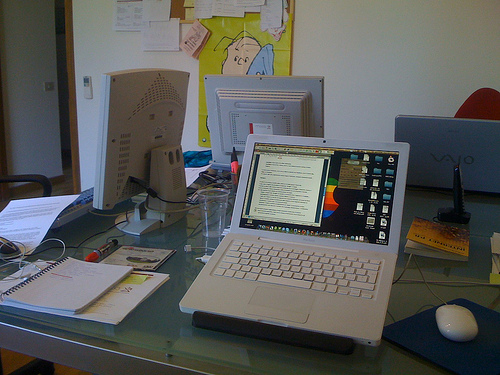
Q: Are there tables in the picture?
A: Yes, there is a table.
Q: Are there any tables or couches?
A: Yes, there is a table.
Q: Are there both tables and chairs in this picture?
A: Yes, there are both a table and a chair.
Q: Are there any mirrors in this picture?
A: No, there are no mirrors.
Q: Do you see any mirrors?
A: No, there are no mirrors.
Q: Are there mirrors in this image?
A: No, there are no mirrors.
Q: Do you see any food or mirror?
A: No, there are no mirrors or food.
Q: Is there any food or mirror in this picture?
A: No, there are no mirrors or food.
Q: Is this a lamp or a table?
A: This is a table.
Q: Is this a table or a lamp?
A: This is a table.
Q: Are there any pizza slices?
A: No, there are no pizza slices.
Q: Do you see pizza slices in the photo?
A: No, there are no pizza slices.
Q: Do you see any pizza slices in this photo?
A: No, there are no pizza slices.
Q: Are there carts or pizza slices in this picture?
A: No, there are no pizza slices or carts.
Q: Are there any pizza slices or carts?
A: No, there are no pizza slices or carts.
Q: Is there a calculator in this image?
A: No, there are no calculators.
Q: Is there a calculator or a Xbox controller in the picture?
A: No, there are no calculators or Xbox controllers.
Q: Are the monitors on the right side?
A: No, the monitors are on the left of the image.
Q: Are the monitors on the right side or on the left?
A: The monitors are on the left of the image.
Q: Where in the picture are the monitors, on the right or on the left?
A: The monitors are on the left of the image.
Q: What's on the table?
A: The monitors are on the table.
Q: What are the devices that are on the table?
A: The devices are monitors.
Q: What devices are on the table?
A: The devices are monitors.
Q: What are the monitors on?
A: The monitors are on the table.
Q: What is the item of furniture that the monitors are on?
A: The piece of furniture is a table.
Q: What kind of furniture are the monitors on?
A: The monitors are on the table.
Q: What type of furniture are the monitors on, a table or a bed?
A: The monitors are on a table.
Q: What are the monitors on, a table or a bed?
A: The monitors are on a table.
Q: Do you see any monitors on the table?
A: Yes, there are monitors on the table.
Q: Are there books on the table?
A: No, there are monitors on the table.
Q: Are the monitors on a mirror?
A: No, the monitors are on the table.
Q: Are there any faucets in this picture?
A: No, there are no faucets.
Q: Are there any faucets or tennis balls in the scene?
A: No, there are no faucets or tennis balls.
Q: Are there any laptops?
A: Yes, there is a laptop.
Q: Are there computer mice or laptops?
A: Yes, there is a laptop.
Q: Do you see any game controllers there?
A: No, there are no game controllers.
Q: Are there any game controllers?
A: No, there are no game controllers.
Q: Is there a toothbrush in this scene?
A: No, there are no toothbrushes.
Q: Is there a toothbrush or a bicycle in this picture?
A: No, there are no toothbrushes or bicycles.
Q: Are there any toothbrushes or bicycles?
A: No, there are no toothbrushes or bicycles.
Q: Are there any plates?
A: No, there are no plates.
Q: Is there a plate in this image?
A: No, there are no plates.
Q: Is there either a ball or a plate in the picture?
A: No, there are no plates or balls.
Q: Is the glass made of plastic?
A: Yes, the glass is made of plastic.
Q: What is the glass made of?
A: The glass is made of plastic.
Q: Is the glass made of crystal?
A: No, the glass is made of plastic.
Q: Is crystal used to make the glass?
A: No, the glass is made of plastic.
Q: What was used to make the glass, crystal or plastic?
A: The glass is made of plastic.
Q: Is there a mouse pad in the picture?
A: Yes, there is a mouse pad.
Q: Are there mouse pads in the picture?
A: Yes, there is a mouse pad.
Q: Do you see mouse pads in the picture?
A: Yes, there is a mouse pad.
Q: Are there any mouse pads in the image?
A: Yes, there is a mouse pad.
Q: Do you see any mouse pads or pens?
A: Yes, there is a mouse pad.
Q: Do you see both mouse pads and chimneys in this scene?
A: No, there is a mouse pad but no chimneys.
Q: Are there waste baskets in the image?
A: No, there are no waste baskets.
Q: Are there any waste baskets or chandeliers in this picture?
A: No, there are no waste baskets or chandeliers.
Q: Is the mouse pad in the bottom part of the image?
A: Yes, the mouse pad is in the bottom of the image.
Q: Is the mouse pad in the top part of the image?
A: No, the mouse pad is in the bottom of the image.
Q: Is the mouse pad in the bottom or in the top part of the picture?
A: The mouse pad is in the bottom of the image.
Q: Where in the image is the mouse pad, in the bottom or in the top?
A: The mouse pad is in the bottom of the image.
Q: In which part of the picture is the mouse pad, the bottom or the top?
A: The mouse pad is in the bottom of the image.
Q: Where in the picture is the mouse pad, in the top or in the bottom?
A: The mouse pad is in the bottom of the image.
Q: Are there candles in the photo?
A: No, there are no candles.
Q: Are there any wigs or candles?
A: No, there are no candles or wigs.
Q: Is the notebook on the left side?
A: Yes, the notebook is on the left of the image.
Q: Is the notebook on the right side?
A: No, the notebook is on the left of the image.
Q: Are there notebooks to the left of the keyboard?
A: Yes, there is a notebook to the left of the keyboard.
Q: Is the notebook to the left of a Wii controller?
A: No, the notebook is to the left of a keyboard.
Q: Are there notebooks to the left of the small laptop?
A: Yes, there is a notebook to the left of the laptop.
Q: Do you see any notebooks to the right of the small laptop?
A: No, the notebook is to the left of the laptop.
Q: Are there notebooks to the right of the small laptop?
A: No, the notebook is to the left of the laptop.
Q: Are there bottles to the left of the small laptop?
A: No, there is a notebook to the left of the laptop.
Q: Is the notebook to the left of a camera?
A: No, the notebook is to the left of the laptop.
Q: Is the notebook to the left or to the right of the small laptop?
A: The notebook is to the left of the laptop.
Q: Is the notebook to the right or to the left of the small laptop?
A: The notebook is to the left of the laptop.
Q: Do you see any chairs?
A: Yes, there is a chair.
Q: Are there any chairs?
A: Yes, there is a chair.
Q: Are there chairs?
A: Yes, there is a chair.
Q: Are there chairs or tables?
A: Yes, there is a chair.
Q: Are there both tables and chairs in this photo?
A: Yes, there are both a chair and a table.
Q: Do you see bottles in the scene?
A: No, there are no bottles.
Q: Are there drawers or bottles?
A: No, there are no bottles or drawers.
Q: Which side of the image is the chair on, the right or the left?
A: The chair is on the right of the image.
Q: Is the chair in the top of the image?
A: Yes, the chair is in the top of the image.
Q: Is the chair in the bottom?
A: No, the chair is in the top of the image.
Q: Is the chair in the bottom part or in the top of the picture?
A: The chair is in the top of the image.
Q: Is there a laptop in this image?
A: Yes, there is a laptop.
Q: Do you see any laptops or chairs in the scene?
A: Yes, there is a laptop.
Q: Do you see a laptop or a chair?
A: Yes, there is a laptop.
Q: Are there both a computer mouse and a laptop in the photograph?
A: Yes, there are both a laptop and a computer mouse.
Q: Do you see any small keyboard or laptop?
A: Yes, there is a small laptop.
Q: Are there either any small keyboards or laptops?
A: Yes, there is a small laptop.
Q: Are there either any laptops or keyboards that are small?
A: Yes, the laptop is small.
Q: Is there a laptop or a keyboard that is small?
A: Yes, the laptop is small.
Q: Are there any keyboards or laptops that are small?
A: Yes, the laptop is small.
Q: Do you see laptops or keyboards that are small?
A: Yes, the laptop is small.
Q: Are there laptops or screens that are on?
A: Yes, the laptop is on.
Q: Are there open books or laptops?
A: Yes, there is an open laptop.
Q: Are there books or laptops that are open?
A: Yes, the laptop is open.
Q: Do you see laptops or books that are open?
A: Yes, the laptop is open.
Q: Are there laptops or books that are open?
A: Yes, the laptop is open.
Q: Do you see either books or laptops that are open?
A: Yes, the laptop is open.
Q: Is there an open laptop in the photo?
A: Yes, there is an open laptop.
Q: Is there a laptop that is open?
A: Yes, there is a laptop that is open.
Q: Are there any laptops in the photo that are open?
A: Yes, there is a laptop that is open.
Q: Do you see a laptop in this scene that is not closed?
A: Yes, there is a open laptop.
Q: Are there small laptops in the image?
A: Yes, there is a small laptop.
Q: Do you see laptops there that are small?
A: Yes, there is a laptop that is small.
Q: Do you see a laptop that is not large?
A: Yes, there is a small laptop.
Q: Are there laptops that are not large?
A: Yes, there is a small laptop.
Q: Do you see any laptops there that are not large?
A: Yes, there is a small laptop.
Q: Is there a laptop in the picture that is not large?
A: Yes, there is a small laptop.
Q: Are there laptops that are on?
A: Yes, there is a laptop that is on.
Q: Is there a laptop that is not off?
A: Yes, there is a laptop that is on.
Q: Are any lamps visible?
A: No, there are no lamps.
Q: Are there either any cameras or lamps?
A: No, there are no lamps or cameras.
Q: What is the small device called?
A: The device is a laptop.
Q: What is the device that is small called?
A: The device is a laptop.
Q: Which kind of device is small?
A: The device is a laptop.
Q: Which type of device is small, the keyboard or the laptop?
A: The laptop is small.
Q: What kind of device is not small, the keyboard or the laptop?
A: The keyboard is not small.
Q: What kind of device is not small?
A: The device is a keyboard.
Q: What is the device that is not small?
A: The device is a keyboard.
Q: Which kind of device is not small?
A: The device is a keyboard.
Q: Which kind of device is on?
A: The device is a laptop.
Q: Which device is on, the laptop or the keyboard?
A: The laptop is on.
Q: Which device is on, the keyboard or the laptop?
A: The laptop is on.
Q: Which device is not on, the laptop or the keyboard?
A: The keyboard is not on.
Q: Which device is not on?
A: The device is a keyboard.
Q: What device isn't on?
A: The device is a keyboard.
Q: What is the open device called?
A: The device is a laptop.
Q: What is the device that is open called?
A: The device is a laptop.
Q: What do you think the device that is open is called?
A: The device is a laptop.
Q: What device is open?
A: The device is a laptop.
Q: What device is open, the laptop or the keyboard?
A: The laptop is open.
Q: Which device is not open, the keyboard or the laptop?
A: The keyboard is not open.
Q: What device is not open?
A: The device is a keyboard.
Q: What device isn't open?
A: The device is a keyboard.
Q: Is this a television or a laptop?
A: This is a laptop.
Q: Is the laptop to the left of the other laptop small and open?
A: Yes, the laptop is small and open.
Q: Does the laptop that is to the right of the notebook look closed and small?
A: No, the laptop is small but open.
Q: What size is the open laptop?
A: The laptop is small.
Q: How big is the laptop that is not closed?
A: The laptop is small.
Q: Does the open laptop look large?
A: No, the laptop is small.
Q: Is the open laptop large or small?
A: The laptop is small.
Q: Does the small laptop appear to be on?
A: Yes, the laptop is on.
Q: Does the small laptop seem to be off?
A: No, the laptop is on.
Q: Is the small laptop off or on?
A: The laptop is on.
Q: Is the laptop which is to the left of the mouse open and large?
A: No, the laptop is open but small.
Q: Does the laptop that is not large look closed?
A: No, the laptop is open.